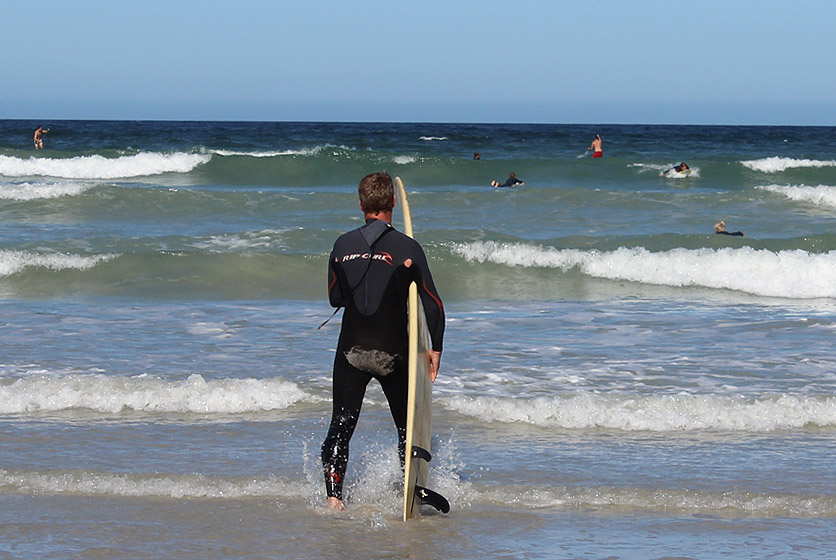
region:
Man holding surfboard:
[317, 168, 448, 520]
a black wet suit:
[324, 219, 445, 496]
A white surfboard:
[394, 173, 447, 520]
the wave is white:
[0, 146, 210, 179]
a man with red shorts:
[584, 128, 598, 153]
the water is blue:
[0, 121, 833, 554]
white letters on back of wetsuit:
[339, 247, 387, 260]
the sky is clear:
[1, 0, 828, 123]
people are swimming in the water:
[0, 117, 832, 554]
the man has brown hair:
[358, 172, 395, 213]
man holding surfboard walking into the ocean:
[320, 170, 450, 521]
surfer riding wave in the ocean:
[32, 124, 47, 150]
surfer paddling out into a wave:
[488, 170, 522, 190]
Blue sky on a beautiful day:
[2, 2, 833, 122]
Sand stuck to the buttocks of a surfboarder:
[340, 344, 399, 376]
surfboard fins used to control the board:
[407, 442, 448, 512]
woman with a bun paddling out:
[710, 219, 744, 235]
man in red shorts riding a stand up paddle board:
[581, 131, 602, 160]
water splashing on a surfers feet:
[296, 423, 475, 531]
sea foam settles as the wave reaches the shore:
[4, 302, 829, 426]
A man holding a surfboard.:
[319, 167, 455, 519]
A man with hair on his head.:
[354, 170, 395, 222]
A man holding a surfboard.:
[397, 173, 432, 522]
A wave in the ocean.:
[2, 133, 826, 215]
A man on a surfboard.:
[481, 169, 527, 197]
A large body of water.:
[1, 123, 833, 556]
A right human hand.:
[420, 342, 441, 381]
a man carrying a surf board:
[311, 159, 462, 536]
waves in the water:
[11, 141, 833, 486]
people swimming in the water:
[458, 127, 752, 252]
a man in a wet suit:
[304, 160, 452, 532]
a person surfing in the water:
[22, 114, 49, 155]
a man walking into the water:
[309, 157, 463, 535]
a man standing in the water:
[311, 157, 454, 524]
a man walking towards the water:
[309, 159, 463, 524]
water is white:
[692, 240, 782, 294]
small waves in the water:
[570, 303, 664, 369]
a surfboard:
[391, 347, 430, 517]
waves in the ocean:
[103, 159, 242, 270]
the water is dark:
[125, 291, 202, 363]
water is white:
[158, 381, 243, 404]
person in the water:
[576, 130, 604, 162]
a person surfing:
[659, 156, 697, 177]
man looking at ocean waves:
[286, 137, 462, 553]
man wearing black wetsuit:
[296, 156, 488, 547]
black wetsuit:
[308, 214, 446, 520]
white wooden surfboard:
[379, 166, 478, 557]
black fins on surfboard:
[410, 429, 450, 529]